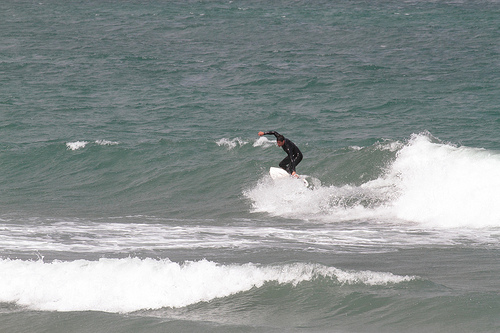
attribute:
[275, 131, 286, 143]
hair — black